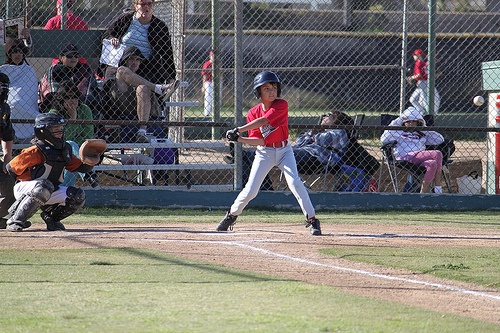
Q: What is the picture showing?
A: It is showing a field.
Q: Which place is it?
A: It is a field.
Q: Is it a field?
A: Yes, it is a field.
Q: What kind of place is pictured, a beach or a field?
A: It is a field.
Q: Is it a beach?
A: No, it is a field.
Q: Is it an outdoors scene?
A: Yes, it is outdoors.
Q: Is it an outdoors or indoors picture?
A: It is outdoors.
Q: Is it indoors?
A: No, it is outdoors.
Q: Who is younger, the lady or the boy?
A: The boy is younger than the lady.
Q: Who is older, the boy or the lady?
A: The lady is older than the boy.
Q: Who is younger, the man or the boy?
A: The boy is younger than the man.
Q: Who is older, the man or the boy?
A: The man is older than the boy.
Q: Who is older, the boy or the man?
A: The man is older than the boy.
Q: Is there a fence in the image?
A: Yes, there is a fence.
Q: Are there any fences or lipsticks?
A: Yes, there is a fence.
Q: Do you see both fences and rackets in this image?
A: No, there is a fence but no rackets.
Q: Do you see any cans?
A: No, there are no cans.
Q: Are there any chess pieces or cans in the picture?
A: No, there are no cans or chess pieces.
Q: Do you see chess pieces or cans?
A: No, there are no cans or chess pieces.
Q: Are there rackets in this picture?
A: No, there are no rackets.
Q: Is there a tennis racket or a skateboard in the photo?
A: No, there are no rackets or skateboards.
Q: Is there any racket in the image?
A: No, there are no rackets.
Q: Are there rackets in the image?
A: No, there are no rackets.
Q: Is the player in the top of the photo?
A: Yes, the player is in the top of the image.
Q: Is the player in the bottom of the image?
A: No, the player is in the top of the image.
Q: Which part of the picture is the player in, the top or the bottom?
A: The player is in the top of the image.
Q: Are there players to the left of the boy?
A: Yes, there is a player to the left of the boy.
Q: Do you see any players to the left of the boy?
A: Yes, there is a player to the left of the boy.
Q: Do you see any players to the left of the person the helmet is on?
A: Yes, there is a player to the left of the boy.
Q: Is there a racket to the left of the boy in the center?
A: No, there is a player to the left of the boy.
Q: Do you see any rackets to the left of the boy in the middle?
A: No, there is a player to the left of the boy.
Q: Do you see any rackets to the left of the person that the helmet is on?
A: No, there is a player to the left of the boy.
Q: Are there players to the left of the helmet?
A: Yes, there is a player to the left of the helmet.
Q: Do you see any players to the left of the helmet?
A: Yes, there is a player to the left of the helmet.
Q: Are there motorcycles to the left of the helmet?
A: No, there is a player to the left of the helmet.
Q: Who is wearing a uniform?
A: The player is wearing a uniform.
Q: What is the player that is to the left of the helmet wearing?
A: The player is wearing a uniform.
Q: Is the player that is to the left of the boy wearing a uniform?
A: Yes, the player is wearing a uniform.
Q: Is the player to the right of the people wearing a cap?
A: No, the player is wearing a uniform.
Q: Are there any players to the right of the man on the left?
A: Yes, there is a player to the right of the man.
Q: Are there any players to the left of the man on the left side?
A: No, the player is to the right of the man.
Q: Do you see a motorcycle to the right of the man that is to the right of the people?
A: No, there is a player to the right of the man.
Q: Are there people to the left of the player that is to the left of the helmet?
A: Yes, there are people to the left of the player.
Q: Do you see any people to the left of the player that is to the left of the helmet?
A: Yes, there are people to the left of the player.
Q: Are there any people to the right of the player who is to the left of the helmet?
A: No, the people are to the left of the player.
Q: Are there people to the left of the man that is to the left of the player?
A: Yes, there are people to the left of the man.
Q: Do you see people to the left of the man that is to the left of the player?
A: Yes, there are people to the left of the man.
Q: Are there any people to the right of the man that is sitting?
A: No, the people are to the left of the man.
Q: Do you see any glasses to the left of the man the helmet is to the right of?
A: No, there are people to the left of the man.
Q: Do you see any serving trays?
A: No, there are no serving trays.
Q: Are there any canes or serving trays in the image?
A: No, there are no serving trays or canes.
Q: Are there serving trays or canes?
A: No, there are no serving trays or canes.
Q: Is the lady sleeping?
A: Yes, the lady is sleeping.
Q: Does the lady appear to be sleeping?
A: Yes, the lady is sleeping.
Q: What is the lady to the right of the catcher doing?
A: The lady is sleeping.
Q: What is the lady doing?
A: The lady is sleeping.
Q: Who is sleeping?
A: The lady is sleeping.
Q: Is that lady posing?
A: No, the lady is sleeping.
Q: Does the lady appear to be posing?
A: No, the lady is sleeping.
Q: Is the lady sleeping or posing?
A: The lady is sleeping.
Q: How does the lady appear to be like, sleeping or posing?
A: The lady is sleeping.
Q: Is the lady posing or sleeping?
A: The lady is sleeping.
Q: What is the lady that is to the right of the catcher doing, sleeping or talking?
A: The lady is sleeping.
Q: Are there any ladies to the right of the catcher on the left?
A: Yes, there is a lady to the right of the catcher.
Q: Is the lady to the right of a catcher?
A: Yes, the lady is to the right of a catcher.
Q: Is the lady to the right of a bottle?
A: No, the lady is to the right of a catcher.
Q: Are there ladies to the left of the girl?
A: Yes, there is a lady to the left of the girl.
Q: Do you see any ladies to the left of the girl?
A: Yes, there is a lady to the left of the girl.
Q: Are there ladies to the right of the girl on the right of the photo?
A: No, the lady is to the left of the girl.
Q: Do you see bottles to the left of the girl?
A: No, there is a lady to the left of the girl.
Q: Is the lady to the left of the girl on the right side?
A: Yes, the lady is to the left of the girl.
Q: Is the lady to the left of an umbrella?
A: No, the lady is to the left of the girl.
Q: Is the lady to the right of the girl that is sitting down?
A: No, the lady is to the left of the girl.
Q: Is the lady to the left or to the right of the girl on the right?
A: The lady is to the left of the girl.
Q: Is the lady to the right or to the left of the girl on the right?
A: The lady is to the left of the girl.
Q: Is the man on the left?
A: Yes, the man is on the left of the image.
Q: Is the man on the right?
A: No, the man is on the left of the image.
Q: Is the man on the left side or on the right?
A: The man is on the left of the image.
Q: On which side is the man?
A: The man is on the left of the image.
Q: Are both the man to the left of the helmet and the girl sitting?
A: Yes, both the man and the girl are sitting.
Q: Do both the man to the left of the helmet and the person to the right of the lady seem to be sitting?
A: Yes, both the man and the girl are sitting.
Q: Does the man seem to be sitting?
A: Yes, the man is sitting.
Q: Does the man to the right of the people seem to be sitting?
A: Yes, the man is sitting.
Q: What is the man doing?
A: The man is sitting.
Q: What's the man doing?
A: The man is sitting.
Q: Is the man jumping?
A: No, the man is sitting.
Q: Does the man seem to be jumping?
A: No, the man is sitting.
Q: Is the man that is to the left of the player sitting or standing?
A: The man is sitting.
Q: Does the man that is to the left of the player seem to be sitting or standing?
A: The man is sitting.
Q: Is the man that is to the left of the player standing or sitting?
A: The man is sitting.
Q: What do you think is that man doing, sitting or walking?
A: The man is sitting.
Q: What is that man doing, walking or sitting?
A: The man is sitting.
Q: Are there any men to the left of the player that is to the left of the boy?
A: Yes, there is a man to the left of the player.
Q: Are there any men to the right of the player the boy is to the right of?
A: No, the man is to the left of the player.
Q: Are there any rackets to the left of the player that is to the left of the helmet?
A: No, there is a man to the left of the player.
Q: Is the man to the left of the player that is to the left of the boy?
A: Yes, the man is to the left of the player.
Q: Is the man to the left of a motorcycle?
A: No, the man is to the left of the player.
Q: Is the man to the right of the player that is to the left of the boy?
A: No, the man is to the left of the player.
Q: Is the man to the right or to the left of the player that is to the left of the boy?
A: The man is to the left of the player.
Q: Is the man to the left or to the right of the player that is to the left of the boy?
A: The man is to the left of the player.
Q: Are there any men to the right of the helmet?
A: No, the man is to the left of the helmet.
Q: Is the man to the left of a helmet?
A: Yes, the man is to the left of a helmet.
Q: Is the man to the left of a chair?
A: No, the man is to the left of a helmet.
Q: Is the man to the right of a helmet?
A: No, the man is to the left of a helmet.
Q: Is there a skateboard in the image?
A: No, there are no skateboards.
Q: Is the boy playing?
A: Yes, the boy is playing.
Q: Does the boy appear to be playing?
A: Yes, the boy is playing.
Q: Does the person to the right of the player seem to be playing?
A: Yes, the boy is playing.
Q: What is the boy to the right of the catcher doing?
A: The boy is playing.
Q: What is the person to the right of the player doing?
A: The boy is playing.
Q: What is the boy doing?
A: The boy is playing.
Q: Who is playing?
A: The boy is playing.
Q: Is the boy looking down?
A: No, the boy is playing.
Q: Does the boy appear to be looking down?
A: No, the boy is playing.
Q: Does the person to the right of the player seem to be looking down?
A: No, the boy is playing.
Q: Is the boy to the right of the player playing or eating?
A: The boy is playing.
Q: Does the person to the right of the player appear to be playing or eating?
A: The boy is playing.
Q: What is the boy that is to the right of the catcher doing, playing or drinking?
A: The boy is playing.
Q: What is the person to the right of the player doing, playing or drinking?
A: The boy is playing.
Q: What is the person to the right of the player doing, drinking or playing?
A: The boy is playing.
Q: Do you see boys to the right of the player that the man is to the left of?
A: Yes, there is a boy to the right of the player.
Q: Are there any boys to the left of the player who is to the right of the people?
A: No, the boy is to the right of the player.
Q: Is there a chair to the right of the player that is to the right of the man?
A: No, there is a boy to the right of the player.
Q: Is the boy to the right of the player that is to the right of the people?
A: Yes, the boy is to the right of the player.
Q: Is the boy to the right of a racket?
A: No, the boy is to the right of the player.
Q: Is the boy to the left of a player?
A: No, the boy is to the right of a player.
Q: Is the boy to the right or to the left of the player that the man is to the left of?
A: The boy is to the right of the player.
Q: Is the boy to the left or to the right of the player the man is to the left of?
A: The boy is to the right of the player.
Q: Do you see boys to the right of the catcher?
A: Yes, there is a boy to the right of the catcher.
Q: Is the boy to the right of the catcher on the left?
A: Yes, the boy is to the right of the catcher.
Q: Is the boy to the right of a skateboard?
A: No, the boy is to the right of the catcher.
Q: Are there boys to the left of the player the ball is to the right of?
A: Yes, there is a boy to the left of the player.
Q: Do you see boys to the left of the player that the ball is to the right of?
A: Yes, there is a boy to the left of the player.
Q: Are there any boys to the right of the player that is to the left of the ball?
A: No, the boy is to the left of the player.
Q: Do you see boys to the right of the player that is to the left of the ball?
A: No, the boy is to the left of the player.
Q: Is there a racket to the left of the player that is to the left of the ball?
A: No, there is a boy to the left of the player.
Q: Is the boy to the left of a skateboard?
A: No, the boy is to the left of a player.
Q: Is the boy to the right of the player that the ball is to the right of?
A: No, the boy is to the left of the player.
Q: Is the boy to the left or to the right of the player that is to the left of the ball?
A: The boy is to the left of the player.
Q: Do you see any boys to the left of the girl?
A: Yes, there is a boy to the left of the girl.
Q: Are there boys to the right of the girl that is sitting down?
A: No, the boy is to the left of the girl.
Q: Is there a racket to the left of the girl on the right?
A: No, there is a boy to the left of the girl.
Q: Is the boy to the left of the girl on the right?
A: Yes, the boy is to the left of the girl.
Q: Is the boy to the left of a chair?
A: No, the boy is to the left of the girl.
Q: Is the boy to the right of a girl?
A: No, the boy is to the left of a girl.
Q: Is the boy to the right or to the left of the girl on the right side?
A: The boy is to the left of the girl.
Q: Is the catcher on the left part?
A: Yes, the catcher is on the left of the image.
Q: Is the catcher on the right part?
A: No, the catcher is on the left of the image.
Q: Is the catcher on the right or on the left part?
A: The catcher is on the left of the image.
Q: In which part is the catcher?
A: The catcher is on the left of the image.